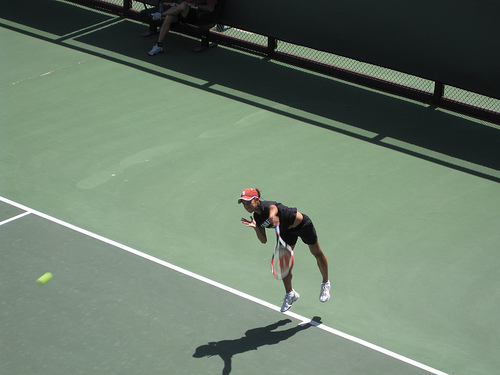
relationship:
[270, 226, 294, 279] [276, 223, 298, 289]
racket holding racket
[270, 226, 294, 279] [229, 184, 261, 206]
racket wearing hat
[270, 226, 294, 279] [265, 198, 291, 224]
racket wearing shirt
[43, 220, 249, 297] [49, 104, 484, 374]
lines on court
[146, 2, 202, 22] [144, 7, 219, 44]
person on bench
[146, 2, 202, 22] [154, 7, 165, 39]
person crossing legs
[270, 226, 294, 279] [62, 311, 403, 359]
racket off ground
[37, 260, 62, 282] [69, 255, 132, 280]
ball in motion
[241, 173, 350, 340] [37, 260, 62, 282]
player hit ball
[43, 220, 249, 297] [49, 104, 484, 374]
lines in court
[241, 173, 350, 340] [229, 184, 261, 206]
player wearing hat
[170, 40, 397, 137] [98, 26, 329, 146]
shadow on ground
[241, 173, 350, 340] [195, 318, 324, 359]
player has shadow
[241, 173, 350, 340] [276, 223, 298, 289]
player holding racket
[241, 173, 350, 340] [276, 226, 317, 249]
player wearing shorts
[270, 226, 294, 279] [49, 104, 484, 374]
racket on court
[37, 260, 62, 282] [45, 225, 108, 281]
ball in air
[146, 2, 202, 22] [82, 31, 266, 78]
person in back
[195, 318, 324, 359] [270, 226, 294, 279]
shadow of racket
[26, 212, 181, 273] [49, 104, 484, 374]
baseline on court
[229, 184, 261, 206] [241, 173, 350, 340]
hat on player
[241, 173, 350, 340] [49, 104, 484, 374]
player hovering over court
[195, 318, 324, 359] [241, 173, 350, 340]
shadow of player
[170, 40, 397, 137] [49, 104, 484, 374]
shadow on court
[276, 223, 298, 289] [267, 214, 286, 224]
racket in hand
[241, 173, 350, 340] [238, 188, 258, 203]
player has hat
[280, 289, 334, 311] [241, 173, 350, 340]
sneakers on player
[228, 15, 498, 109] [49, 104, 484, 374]
fence behind court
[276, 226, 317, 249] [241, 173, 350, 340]
shorts on player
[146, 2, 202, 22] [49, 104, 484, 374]
person on court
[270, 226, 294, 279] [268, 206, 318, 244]
racket in clothing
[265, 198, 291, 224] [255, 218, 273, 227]
shirt has writing